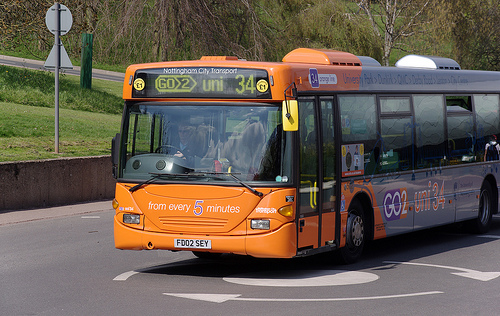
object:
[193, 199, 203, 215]
number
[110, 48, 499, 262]
bus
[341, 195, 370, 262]
wheel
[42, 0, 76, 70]
sign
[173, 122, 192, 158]
driver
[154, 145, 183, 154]
steering wheel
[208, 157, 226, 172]
object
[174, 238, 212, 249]
plate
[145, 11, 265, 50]
trees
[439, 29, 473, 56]
leaves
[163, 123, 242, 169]
glass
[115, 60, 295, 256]
front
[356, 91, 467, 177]
windows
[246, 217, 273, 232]
headlights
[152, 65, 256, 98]
display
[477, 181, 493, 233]
wheels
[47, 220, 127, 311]
asphault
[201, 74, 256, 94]
lettering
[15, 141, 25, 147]
grass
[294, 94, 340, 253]
door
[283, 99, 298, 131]
mirror